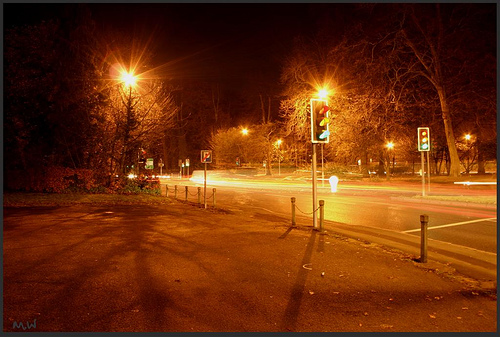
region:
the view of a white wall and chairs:
[276, 270, 286, 297]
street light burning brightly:
[113, 63, 144, 100]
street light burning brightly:
[303, 79, 343, 111]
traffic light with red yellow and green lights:
[308, 97, 333, 142]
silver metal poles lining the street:
[146, 165, 433, 263]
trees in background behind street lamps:
[88, 12, 479, 174]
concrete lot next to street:
[7, 202, 462, 323]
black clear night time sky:
[19, 5, 499, 136]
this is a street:
[85, 48, 439, 282]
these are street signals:
[270, 71, 384, 208]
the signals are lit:
[270, 40, 407, 205]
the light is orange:
[42, 34, 256, 171]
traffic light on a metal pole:
[309, 99, 329, 226]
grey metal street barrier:
[420, 212, 427, 260]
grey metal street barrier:
[319, 199, 324, 229]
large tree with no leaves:
[319, 0, 467, 175]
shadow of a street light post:
[280, 225, 318, 333]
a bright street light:
[119, 70, 140, 90]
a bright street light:
[311, 83, 336, 101]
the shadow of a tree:
[37, 201, 274, 336]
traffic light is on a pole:
[308, 96, 329, 231]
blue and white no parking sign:
[198, 145, 214, 208]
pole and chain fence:
[161, 183, 218, 213]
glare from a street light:
[105, 43, 167, 95]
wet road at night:
[141, 177, 498, 254]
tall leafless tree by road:
[373, 10, 469, 176]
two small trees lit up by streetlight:
[207, 124, 280, 176]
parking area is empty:
[2, 203, 497, 335]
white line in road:
[398, 208, 498, 233]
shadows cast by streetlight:
[10, 203, 266, 330]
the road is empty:
[139, 223, 316, 313]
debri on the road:
[365, 292, 447, 328]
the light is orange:
[406, 123, 438, 155]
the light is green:
[408, 129, 444, 164]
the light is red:
[402, 115, 447, 170]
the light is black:
[408, 122, 437, 156]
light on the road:
[314, 162, 350, 199]